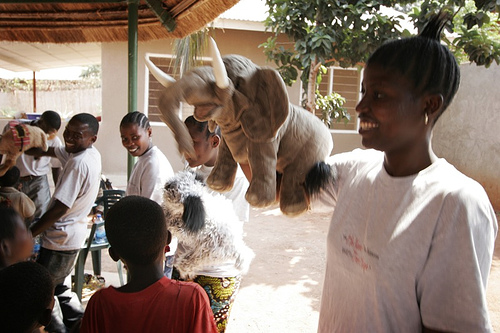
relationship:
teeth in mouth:
[359, 119, 399, 135] [351, 114, 385, 140]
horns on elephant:
[205, 36, 230, 89] [143, 35, 334, 216]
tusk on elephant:
[137, 47, 180, 89] [143, 35, 334, 216]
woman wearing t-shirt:
[238, 32, 498, 329] [247, 137, 484, 332]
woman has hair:
[311, 6, 498, 331] [360, 3, 464, 132]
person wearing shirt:
[234, 31, 494, 328] [306, 145, 496, 331]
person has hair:
[292, 15, 482, 328] [362, 5, 464, 100]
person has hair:
[27, 110, 105, 332] [73, 110, 109, 138]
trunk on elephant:
[164, 81, 201, 166] [143, 35, 334, 216]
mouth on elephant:
[189, 98, 217, 118] [143, 35, 334, 216]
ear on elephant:
[235, 64, 295, 148] [153, 43, 340, 208]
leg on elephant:
[238, 139, 284, 210] [132, 30, 340, 226]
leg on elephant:
[273, 164, 314, 223] [132, 30, 340, 226]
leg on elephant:
[200, 143, 238, 197] [132, 30, 340, 226]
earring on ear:
[424, 113, 429, 125] [425, 91, 446, 116]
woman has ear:
[137, 5, 485, 327] [425, 91, 446, 116]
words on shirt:
[339, 234, 381, 272] [321, 147, 498, 332]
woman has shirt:
[238, 32, 498, 329] [321, 147, 498, 332]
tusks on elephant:
[140, 37, 234, 89] [216, 52, 329, 214]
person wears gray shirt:
[88, 109, 199, 231] [108, 150, 183, 207]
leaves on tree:
[294, 14, 329, 64] [274, 0, 496, 59]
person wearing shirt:
[27, 110, 105, 332] [39, 143, 104, 251]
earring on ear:
[421, 113, 430, 127] [425, 91, 445, 116]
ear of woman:
[425, 91, 445, 116] [329, 51, 497, 331]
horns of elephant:
[133, 52, 178, 81] [144, 35, 336, 217]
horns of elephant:
[195, 33, 235, 88] [144, 35, 336, 217]